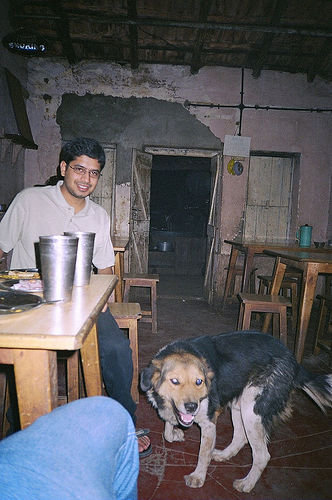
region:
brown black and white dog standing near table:
[129, 327, 329, 493]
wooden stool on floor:
[232, 282, 290, 376]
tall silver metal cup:
[29, 228, 75, 302]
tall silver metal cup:
[58, 226, 92, 283]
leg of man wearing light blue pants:
[0, 389, 147, 499]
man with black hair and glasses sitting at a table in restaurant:
[1, 133, 158, 460]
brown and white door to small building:
[124, 140, 157, 305]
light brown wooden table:
[0, 258, 128, 498]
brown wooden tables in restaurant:
[209, 235, 330, 392]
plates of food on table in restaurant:
[0, 256, 53, 319]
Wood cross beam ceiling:
[9, 0, 328, 86]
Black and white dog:
[133, 319, 326, 488]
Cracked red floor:
[128, 398, 327, 490]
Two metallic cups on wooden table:
[32, 226, 99, 305]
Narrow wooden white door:
[241, 148, 304, 294]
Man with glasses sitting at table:
[5, 127, 143, 339]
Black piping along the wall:
[175, 66, 330, 146]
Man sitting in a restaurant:
[9, 123, 323, 324]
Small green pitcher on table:
[292, 219, 316, 248]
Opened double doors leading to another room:
[128, 138, 225, 301]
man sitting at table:
[14, 133, 131, 326]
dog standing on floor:
[148, 332, 295, 491]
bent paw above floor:
[159, 424, 184, 454]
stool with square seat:
[233, 287, 296, 324]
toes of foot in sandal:
[134, 431, 156, 457]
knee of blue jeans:
[62, 405, 119, 467]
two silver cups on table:
[37, 227, 97, 314]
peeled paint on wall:
[186, 110, 218, 135]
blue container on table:
[292, 220, 317, 250]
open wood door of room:
[120, 141, 166, 265]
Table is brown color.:
[235, 235, 325, 282]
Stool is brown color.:
[221, 284, 289, 342]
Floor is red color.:
[168, 438, 260, 498]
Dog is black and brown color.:
[148, 336, 306, 475]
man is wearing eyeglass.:
[66, 160, 113, 195]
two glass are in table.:
[34, 226, 104, 304]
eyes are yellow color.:
[162, 372, 210, 395]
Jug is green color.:
[299, 222, 316, 249]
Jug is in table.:
[291, 226, 315, 255]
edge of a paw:
[179, 475, 199, 487]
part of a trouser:
[79, 449, 131, 496]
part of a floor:
[264, 433, 285, 460]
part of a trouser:
[124, 387, 136, 412]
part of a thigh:
[257, 379, 275, 401]